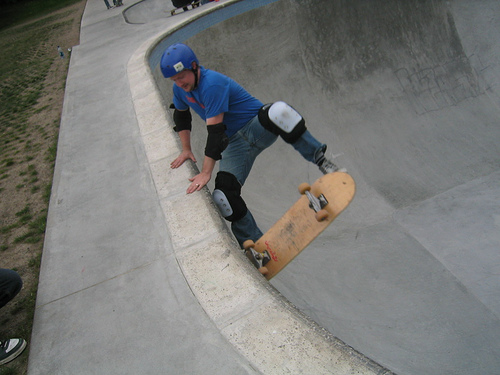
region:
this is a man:
[158, 43, 340, 253]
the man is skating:
[142, 32, 342, 257]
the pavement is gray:
[41, 212, 186, 372]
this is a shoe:
[2, 338, 23, 372]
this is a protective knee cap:
[252, 105, 314, 150]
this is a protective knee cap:
[194, 175, 258, 249]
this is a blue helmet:
[150, 32, 210, 97]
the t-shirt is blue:
[158, 65, 248, 130]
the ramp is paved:
[219, 18, 484, 320]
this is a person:
[141, 26, 343, 263]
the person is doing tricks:
[157, 23, 315, 263]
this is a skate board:
[237, 169, 374, 279]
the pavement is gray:
[58, 99, 139, 187]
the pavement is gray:
[52, 189, 182, 306]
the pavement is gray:
[81, 281, 228, 369]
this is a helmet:
[148, 38, 203, 95]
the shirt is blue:
[171, 71, 251, 131]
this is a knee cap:
[264, 96, 328, 161]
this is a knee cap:
[200, 173, 251, 233]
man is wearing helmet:
[143, 33, 257, 153]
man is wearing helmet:
[125, 20, 213, 115]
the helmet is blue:
[143, 28, 208, 85]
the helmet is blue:
[155, 48, 206, 106]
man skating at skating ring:
[127, 36, 388, 298]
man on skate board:
[221, 162, 369, 286]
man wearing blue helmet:
[136, 35, 231, 95]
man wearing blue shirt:
[157, 61, 284, 151]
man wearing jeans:
[208, 89, 365, 258]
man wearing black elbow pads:
[204, 107, 231, 179]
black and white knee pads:
[250, 87, 322, 159]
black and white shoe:
[0, 318, 31, 373]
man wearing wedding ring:
[188, 173, 205, 204]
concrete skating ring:
[98, 0, 498, 374]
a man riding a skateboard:
[155, 39, 360, 283]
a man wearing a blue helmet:
[160, 38, 202, 96]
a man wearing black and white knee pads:
[260, 102, 310, 137]